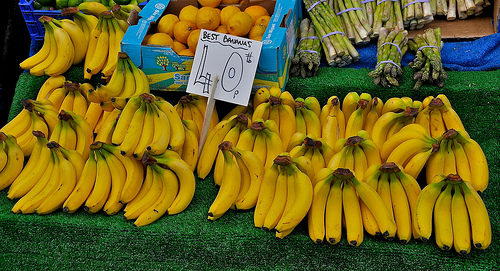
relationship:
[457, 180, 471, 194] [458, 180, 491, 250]
green stem on banana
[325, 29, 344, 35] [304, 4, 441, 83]
bands on vegetables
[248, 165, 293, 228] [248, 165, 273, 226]
banana next to banana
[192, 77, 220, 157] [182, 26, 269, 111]
stick holding sign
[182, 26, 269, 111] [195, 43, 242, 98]
sign with price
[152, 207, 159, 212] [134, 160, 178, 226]
spot on banana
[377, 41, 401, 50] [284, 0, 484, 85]
rubber bands on asparagus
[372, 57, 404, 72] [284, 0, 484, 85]
rubber bands on asparagus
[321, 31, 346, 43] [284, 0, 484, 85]
bands on asparagus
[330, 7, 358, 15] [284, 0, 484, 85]
rubber bands on asparagus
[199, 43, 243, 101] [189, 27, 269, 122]
price on sign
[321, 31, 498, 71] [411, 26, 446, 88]
tarp under asparagus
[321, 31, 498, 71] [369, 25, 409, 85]
tarp under asparagus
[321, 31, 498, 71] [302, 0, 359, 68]
tarp under asparagus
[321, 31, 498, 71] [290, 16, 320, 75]
tarp under asparagus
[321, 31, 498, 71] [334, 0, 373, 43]
tarp under asparagus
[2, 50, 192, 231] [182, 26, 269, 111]
bananas near sign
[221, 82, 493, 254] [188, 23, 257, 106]
bananas near sign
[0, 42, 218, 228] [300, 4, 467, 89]
bananas near veggies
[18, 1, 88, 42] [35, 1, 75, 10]
box has limes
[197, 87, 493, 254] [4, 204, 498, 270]
bananas on grass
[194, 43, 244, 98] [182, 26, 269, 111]
number on sign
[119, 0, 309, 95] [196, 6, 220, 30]
box has fruit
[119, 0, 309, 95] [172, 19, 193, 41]
box has orange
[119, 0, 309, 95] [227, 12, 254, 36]
box has fruit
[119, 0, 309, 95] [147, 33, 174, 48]
box has fruit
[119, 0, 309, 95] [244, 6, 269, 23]
box has fruit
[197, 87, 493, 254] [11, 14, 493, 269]
bananas in stand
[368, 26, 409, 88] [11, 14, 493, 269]
asparagus in stand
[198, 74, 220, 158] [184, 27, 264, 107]
stick on sign